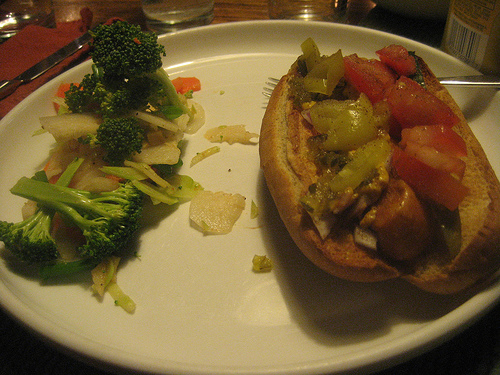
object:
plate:
[0, 18, 498, 375]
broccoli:
[9, 175, 147, 259]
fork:
[260, 74, 498, 100]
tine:
[266, 74, 282, 84]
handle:
[434, 74, 500, 87]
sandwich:
[258, 34, 499, 297]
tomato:
[376, 42, 419, 75]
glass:
[137, 0, 218, 32]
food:
[202, 123, 257, 145]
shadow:
[258, 163, 500, 333]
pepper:
[299, 37, 322, 72]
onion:
[354, 226, 376, 251]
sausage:
[367, 176, 430, 261]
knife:
[0, 22, 108, 101]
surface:
[210, 2, 270, 24]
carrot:
[170, 76, 199, 93]